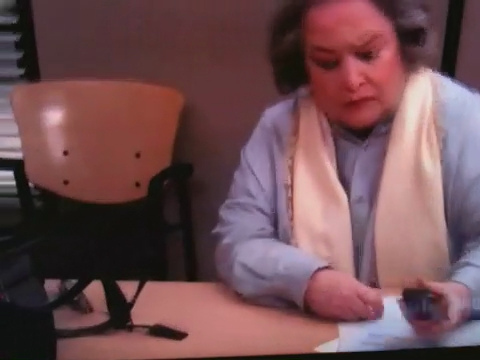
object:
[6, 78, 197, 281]
chair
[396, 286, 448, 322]
phone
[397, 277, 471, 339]
hand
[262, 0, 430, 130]
head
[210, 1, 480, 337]
woman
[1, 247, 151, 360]
bag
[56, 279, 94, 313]
glasses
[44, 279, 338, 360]
table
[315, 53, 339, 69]
eye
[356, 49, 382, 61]
eye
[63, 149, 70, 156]
bolt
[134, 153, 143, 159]
bolt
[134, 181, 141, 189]
bolt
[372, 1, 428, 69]
hair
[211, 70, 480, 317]
shirt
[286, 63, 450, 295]
scarf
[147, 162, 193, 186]
arm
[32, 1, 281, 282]
wall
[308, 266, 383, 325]
hand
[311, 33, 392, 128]
face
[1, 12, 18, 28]
blinds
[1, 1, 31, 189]
window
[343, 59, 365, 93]
nose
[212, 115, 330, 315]
arm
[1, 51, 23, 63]
blinds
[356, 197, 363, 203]
button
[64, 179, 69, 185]
bolt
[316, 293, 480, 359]
paper